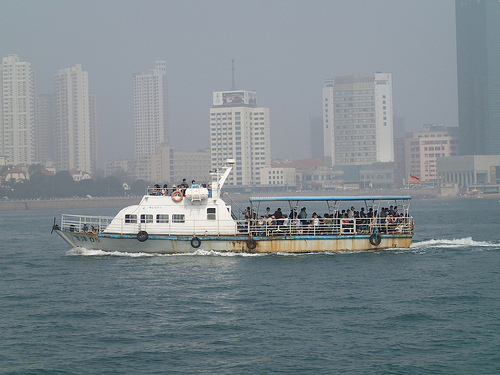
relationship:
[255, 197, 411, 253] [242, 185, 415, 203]
shelter with blue top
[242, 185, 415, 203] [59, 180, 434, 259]
blue top on back of boat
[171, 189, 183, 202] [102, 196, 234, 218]
float attached to side of cabin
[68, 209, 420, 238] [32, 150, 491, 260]
railings on boat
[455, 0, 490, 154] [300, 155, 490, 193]
black building along shoreline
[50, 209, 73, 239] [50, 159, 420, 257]
tip of a boat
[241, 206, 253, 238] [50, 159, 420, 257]
person on boat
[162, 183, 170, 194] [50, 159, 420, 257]
person on boat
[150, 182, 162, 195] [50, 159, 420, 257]
person on boat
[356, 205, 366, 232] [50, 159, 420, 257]
person on boat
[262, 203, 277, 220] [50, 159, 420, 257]
person on boat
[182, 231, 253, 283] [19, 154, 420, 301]
object on boat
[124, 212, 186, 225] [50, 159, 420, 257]
windows on side of boat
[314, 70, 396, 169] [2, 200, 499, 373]
building near water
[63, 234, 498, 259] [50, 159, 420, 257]
wave caused by boat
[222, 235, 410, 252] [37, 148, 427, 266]
side on boat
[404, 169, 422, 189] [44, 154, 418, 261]
flag on boat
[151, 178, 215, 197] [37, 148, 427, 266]
people on boat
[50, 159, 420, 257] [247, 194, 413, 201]
boat has shelter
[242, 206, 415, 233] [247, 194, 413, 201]
people under shelter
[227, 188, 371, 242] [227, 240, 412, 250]
rust spots on bottom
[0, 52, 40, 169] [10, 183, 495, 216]
building on shoreline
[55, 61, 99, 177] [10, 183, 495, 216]
building on shoreline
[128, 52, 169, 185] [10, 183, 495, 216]
building on shoreline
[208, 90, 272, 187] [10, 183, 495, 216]
building on shoreline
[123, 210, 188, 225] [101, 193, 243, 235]
windows on cabin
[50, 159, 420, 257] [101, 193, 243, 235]
boat has cabin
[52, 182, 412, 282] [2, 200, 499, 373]
boat skimming through water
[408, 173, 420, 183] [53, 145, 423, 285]
flag on back of boat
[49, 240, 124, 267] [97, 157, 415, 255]
waves underneath boat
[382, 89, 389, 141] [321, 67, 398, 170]
window on building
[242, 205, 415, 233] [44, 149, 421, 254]
people on boat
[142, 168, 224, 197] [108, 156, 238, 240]
people on boat's cabin